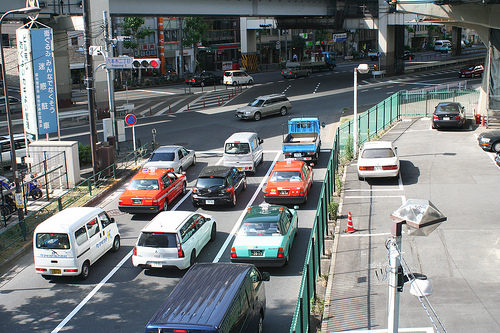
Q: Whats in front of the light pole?
A: White car.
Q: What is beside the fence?
A: Cars.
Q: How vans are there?
A: One.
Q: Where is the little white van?
A: Leftside.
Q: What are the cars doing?
A: At alight.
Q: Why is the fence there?
A: To seperate lanes.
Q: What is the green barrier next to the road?
A: A fence.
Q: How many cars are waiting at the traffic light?
A: 10.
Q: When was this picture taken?
A: During daylight.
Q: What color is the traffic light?
A: Red.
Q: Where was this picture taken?
A: China.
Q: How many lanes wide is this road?
A: 3.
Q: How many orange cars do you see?
A: 2.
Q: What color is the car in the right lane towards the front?
A: Blue.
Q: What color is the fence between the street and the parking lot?
A: Green.